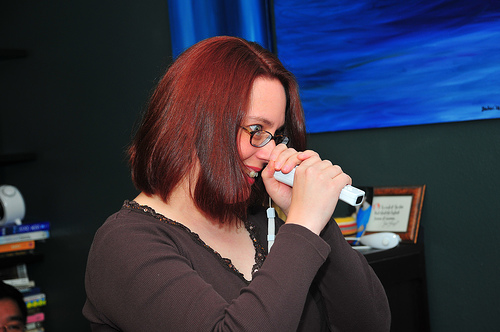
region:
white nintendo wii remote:
[273, 163, 366, 210]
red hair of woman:
[123, 30, 315, 225]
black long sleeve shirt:
[82, 193, 396, 330]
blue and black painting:
[163, 0, 496, 151]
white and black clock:
[0, 185, 32, 225]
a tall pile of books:
[0, 220, 53, 329]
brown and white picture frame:
[365, 184, 427, 244]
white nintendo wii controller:
[356, 225, 401, 255]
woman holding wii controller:
[76, 30, 392, 329]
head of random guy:
[0, 278, 32, 327]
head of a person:
[149, 25, 303, 206]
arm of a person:
[146, 238, 304, 330]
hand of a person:
[292, 151, 377, 242]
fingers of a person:
[289, 162, 361, 193]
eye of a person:
[230, 113, 268, 150]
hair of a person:
[149, 53, 227, 134]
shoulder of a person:
[97, 195, 175, 273]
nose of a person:
[259, 139, 280, 164]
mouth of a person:
[225, 165, 257, 183]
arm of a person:
[310, 233, 400, 320]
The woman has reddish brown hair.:
[103, 20, 388, 230]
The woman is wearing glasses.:
[111, 27, 357, 224]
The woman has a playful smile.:
[131, 30, 314, 218]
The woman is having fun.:
[77, 18, 389, 310]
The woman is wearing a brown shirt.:
[67, 18, 398, 323]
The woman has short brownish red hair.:
[90, 25, 387, 300]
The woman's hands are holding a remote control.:
[265, 139, 358, 212]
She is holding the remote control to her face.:
[106, 34, 433, 265]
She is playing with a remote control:
[91, 22, 399, 270]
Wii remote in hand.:
[266, 145, 368, 208]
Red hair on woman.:
[127, 24, 314, 212]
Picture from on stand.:
[365, 177, 427, 245]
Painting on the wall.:
[162, 0, 499, 147]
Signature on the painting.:
[477, 100, 497, 111]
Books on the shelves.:
[0, 220, 46, 326]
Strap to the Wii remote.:
[256, 190, 281, 265]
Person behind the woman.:
[0, 277, 30, 328]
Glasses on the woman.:
[122, 30, 308, 227]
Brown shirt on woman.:
[79, 28, 413, 328]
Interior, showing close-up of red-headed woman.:
[2, 1, 499, 331]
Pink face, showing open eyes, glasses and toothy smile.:
[241, 84, 275, 191]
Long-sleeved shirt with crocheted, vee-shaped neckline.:
[101, 198, 388, 330]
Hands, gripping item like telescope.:
[274, 145, 368, 229]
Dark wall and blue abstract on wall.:
[69, 3, 498, 143]